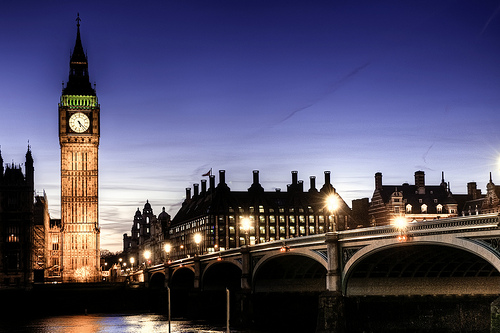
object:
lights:
[70, 62, 87, 65]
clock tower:
[57, 12, 100, 282]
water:
[0, 304, 357, 332]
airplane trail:
[274, 58, 374, 124]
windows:
[219, 206, 325, 249]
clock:
[69, 112, 91, 134]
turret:
[440, 171, 459, 214]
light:
[322, 191, 342, 212]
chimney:
[414, 170, 426, 186]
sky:
[114, 1, 500, 150]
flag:
[202, 170, 211, 177]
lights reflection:
[46, 315, 228, 332]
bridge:
[140, 212, 500, 318]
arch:
[146, 271, 165, 287]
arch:
[170, 265, 195, 288]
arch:
[197, 259, 243, 292]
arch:
[249, 248, 332, 294]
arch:
[336, 234, 499, 297]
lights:
[70, 214, 256, 277]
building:
[122, 167, 500, 264]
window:
[229, 236, 236, 248]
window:
[318, 215, 324, 223]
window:
[238, 216, 252, 230]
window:
[218, 215, 224, 223]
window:
[329, 215, 333, 222]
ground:
[116, 0, 500, 166]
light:
[389, 214, 409, 231]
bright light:
[389, 212, 406, 230]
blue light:
[28, 315, 225, 332]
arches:
[147, 236, 500, 298]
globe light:
[192, 232, 204, 244]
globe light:
[162, 242, 174, 253]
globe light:
[141, 250, 152, 260]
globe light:
[128, 254, 135, 263]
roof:
[164, 169, 352, 226]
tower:
[56, 10, 100, 282]